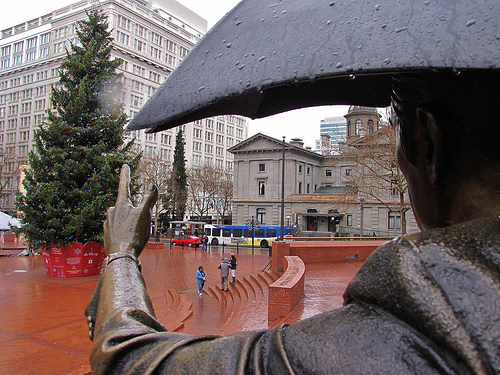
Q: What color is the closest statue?
A: Bronze.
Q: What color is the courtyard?
A: Orange.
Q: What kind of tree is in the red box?
A: Christmas.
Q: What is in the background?
A: City.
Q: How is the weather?
A: Wet.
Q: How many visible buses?
A: 1.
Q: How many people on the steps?
A: 3.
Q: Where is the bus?
A: On the street.